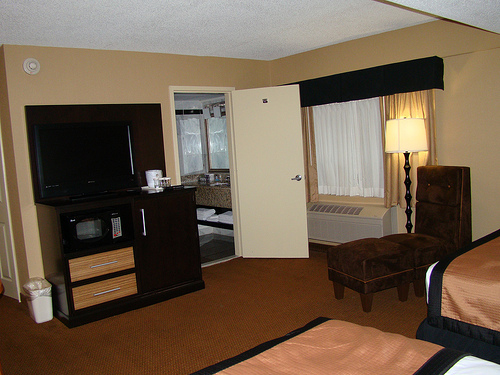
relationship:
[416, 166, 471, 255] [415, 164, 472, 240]
chair with backrest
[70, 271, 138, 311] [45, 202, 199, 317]
drawer on cabinet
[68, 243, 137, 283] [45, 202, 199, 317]
drawer on cabinet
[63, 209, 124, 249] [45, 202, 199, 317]
microwave on cabinet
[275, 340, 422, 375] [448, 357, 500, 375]
throw on bed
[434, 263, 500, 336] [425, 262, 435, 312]
throw on bed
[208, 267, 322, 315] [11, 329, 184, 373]
carpet on floor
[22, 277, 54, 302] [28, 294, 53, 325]
bag in trash-can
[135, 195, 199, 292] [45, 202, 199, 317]
door on cabinet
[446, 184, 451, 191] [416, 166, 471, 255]
button on chair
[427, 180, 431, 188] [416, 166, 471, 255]
button on chair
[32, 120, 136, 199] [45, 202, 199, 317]
tv on cabinet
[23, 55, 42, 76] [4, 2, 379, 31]
smoke-detector near ceiling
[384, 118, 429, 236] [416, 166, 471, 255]
lamp near chair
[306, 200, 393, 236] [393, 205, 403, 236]
ac on wall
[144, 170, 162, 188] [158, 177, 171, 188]
bucket and glasses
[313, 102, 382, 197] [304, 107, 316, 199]
curtain between drapes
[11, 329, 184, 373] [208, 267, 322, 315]
floor has carpet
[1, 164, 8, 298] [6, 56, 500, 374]
door to room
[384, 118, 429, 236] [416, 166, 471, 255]
lamp by chair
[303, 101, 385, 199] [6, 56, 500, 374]
window of room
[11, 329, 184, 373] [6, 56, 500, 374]
floor of room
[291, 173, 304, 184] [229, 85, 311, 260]
handle of door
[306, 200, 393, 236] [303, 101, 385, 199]
ac in front of window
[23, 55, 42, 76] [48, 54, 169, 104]
smoke-detector on wall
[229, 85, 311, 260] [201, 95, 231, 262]
door to bathroom